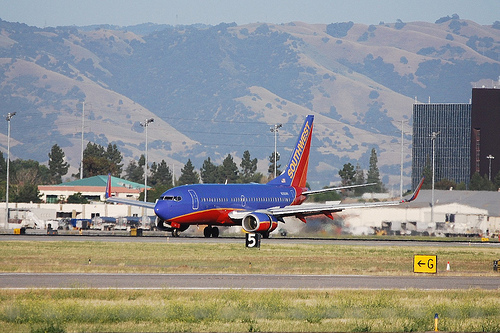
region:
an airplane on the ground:
[105, 133, 445, 320]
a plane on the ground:
[112, 101, 425, 331]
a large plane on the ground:
[126, 114, 415, 313]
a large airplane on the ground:
[147, 101, 363, 286]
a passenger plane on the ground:
[152, 121, 392, 298]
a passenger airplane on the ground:
[117, 111, 350, 267]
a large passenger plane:
[155, 110, 317, 263]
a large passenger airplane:
[108, 138, 388, 296]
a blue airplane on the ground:
[182, 115, 339, 235]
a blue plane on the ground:
[87, 99, 499, 324]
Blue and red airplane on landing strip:
[152, 113, 427, 240]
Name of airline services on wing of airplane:
[285, 119, 310, 178]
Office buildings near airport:
[408, 86, 499, 193]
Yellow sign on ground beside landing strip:
[408, 253, 440, 275]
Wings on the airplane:
[274, 173, 431, 217]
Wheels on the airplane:
[168, 224, 271, 243]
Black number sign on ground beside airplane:
[240, 232, 264, 249]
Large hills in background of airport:
[2, 10, 499, 196]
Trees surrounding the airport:
[1, 140, 497, 205]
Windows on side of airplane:
[154, 194, 296, 205]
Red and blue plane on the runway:
[124, 81, 360, 254]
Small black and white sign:
[236, 222, 268, 257]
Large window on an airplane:
[151, 191, 182, 206]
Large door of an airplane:
[185, 178, 202, 214]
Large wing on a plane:
[263, 198, 440, 231]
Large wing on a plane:
[97, 166, 157, 219]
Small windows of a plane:
[197, 194, 218, 206]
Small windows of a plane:
[212, 192, 239, 212]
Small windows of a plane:
[235, 194, 262, 206]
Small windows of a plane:
[256, 189, 293, 205]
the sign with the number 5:
[244, 231, 259, 246]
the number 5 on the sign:
[247, 233, 254, 246]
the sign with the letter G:
[412, 255, 434, 271]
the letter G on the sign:
[427, 258, 434, 269]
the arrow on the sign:
[415, 259, 425, 268]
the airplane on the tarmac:
[100, 113, 425, 239]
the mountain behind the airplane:
[0, 14, 499, 192]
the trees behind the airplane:
[0, 141, 499, 201]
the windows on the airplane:
[197, 195, 292, 202]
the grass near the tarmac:
[0, 239, 499, 331]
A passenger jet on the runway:
[103, 115, 425, 237]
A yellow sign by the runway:
[412, 253, 440, 273]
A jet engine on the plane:
[240, 211, 278, 233]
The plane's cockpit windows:
[155, 193, 182, 201]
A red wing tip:
[403, 177, 427, 200]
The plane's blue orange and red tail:
[269, 113, 319, 193]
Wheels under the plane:
[204, 223, 219, 238]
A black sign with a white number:
[245, 231, 261, 247]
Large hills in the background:
[0, 13, 498, 185]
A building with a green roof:
[35, 172, 153, 197]